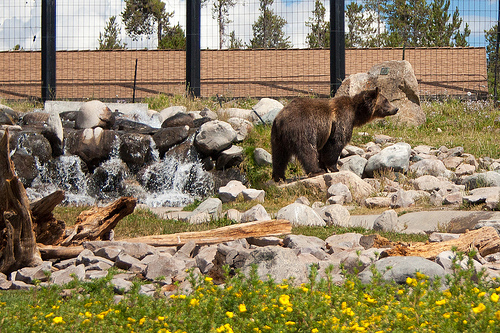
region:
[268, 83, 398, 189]
brown bear standing in enclosure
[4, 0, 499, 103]
black metal fence with wooden posts for support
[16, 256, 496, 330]
small green field of yellow buttercup flowers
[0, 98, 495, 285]
mounds of rocks for climbing and sitting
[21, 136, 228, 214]
waterfall gushing from rock design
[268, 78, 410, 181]
bear walking across rocks away from water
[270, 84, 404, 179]
bear in a cage at a zoo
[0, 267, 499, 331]
small bright yellow flowers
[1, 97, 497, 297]
various sized rocks in the bear's cage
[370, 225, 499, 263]
short brown log laying among the rocks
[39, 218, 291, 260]
long brown log laying among the rocks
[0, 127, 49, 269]
tree stump beyond the flowers and next to the rocks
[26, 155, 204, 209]
water contained by rocks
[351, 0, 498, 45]
bright blue sky outside the cage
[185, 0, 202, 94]
thick black post on the cage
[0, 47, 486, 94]
low brick wall outside the cage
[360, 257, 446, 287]
large rock in enclosure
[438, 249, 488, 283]
large rock in enclosure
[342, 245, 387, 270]
large rock in enclosure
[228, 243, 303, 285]
large rock in enclosure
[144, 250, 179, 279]
large rock in enclosure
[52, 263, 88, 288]
large rock in enclosure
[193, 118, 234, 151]
large rock in enclosure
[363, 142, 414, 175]
large rock in enclosure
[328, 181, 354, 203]
large rock in enclosure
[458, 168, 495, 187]
large rock in enclosure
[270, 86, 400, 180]
a large brown bear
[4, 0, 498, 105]
a black metal fence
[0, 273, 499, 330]
a patch of wild yellow flowers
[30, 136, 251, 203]
a small stone waterfall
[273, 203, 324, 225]
a large white stone boulder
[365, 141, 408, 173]
a large white stone boulder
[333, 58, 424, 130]
a large tan stone boulder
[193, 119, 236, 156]
a large tan stone boulder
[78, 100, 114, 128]
a large tan stone boulder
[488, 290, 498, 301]
yellow flower in field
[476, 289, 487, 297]
yellow flower in field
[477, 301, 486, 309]
yellow flower in field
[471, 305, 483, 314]
yellow flower in field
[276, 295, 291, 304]
yellow flower in field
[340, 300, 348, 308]
yellow flower in field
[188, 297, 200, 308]
yellow flower in field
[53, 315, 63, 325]
yellow flower in field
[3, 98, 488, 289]
grey and white pile of rocks in enclosure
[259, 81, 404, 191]
black bear id crossing field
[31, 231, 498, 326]
many yellow buttercups and flowers, in general, there is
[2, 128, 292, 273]
brown drift wood to side of bear